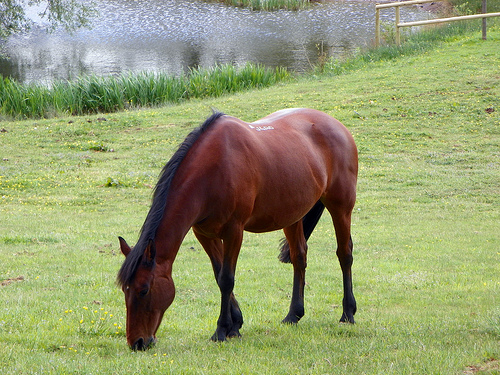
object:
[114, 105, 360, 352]
horse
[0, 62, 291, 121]
weeds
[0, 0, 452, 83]
pond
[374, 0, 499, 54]
railing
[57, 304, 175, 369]
flowers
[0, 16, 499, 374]
grass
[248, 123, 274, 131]
brand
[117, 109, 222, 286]
mane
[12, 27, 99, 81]
reflection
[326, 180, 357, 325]
legs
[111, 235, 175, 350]
head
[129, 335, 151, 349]
nose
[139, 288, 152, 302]
left eye